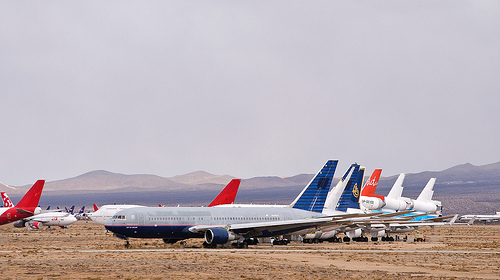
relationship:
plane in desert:
[88, 160, 343, 240] [1, 228, 496, 278]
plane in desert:
[322, 163, 365, 234] [1, 228, 496, 278]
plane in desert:
[376, 170, 418, 227] [1, 228, 496, 278]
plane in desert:
[404, 172, 446, 227] [1, 228, 496, 278]